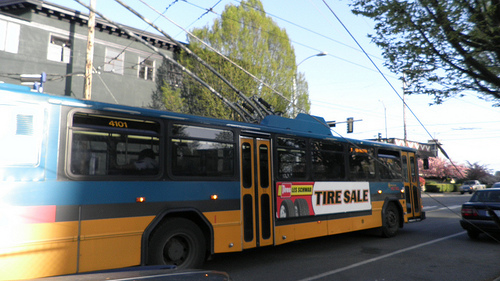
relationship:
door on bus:
[240, 135, 272, 246] [2, 85, 428, 270]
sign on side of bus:
[273, 180, 375, 218] [2, 85, 428, 270]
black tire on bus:
[153, 220, 204, 267] [2, 85, 428, 270]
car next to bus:
[460, 191, 499, 232] [2, 85, 428, 270]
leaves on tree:
[373, 19, 442, 70] [351, 0, 499, 106]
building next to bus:
[0, 5, 295, 117] [2, 85, 428, 270]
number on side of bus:
[105, 120, 134, 128] [2, 85, 428, 270]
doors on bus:
[240, 135, 272, 246] [2, 85, 428, 270]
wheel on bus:
[378, 205, 407, 228] [2, 85, 428, 270]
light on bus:
[208, 193, 220, 200] [2, 85, 428, 270]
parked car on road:
[459, 181, 484, 192] [245, 194, 499, 280]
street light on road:
[324, 115, 363, 132] [245, 194, 499, 280]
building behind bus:
[0, 5, 295, 117] [2, 85, 428, 270]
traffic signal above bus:
[324, 115, 363, 132] [2, 85, 428, 270]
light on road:
[309, 49, 328, 60] [245, 194, 499, 280]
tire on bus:
[153, 220, 204, 267] [2, 85, 428, 270]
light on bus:
[375, 187, 387, 194] [2, 85, 428, 270]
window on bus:
[72, 127, 159, 173] [2, 85, 428, 270]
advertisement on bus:
[273, 180, 375, 218] [2, 85, 428, 270]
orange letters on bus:
[103, 115, 136, 128] [2, 85, 428, 270]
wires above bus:
[47, 8, 381, 107] [2, 85, 428, 270]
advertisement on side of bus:
[273, 180, 375, 218] [2, 85, 428, 270]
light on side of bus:
[208, 193, 220, 200] [2, 85, 428, 270]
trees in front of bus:
[412, 156, 473, 184] [2, 85, 428, 270]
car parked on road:
[460, 191, 499, 232] [245, 194, 499, 280]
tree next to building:
[172, 14, 305, 113] [0, 5, 290, 113]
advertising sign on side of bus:
[273, 180, 375, 218] [2, 85, 428, 270]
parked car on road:
[454, 180, 483, 194] [245, 194, 499, 280]